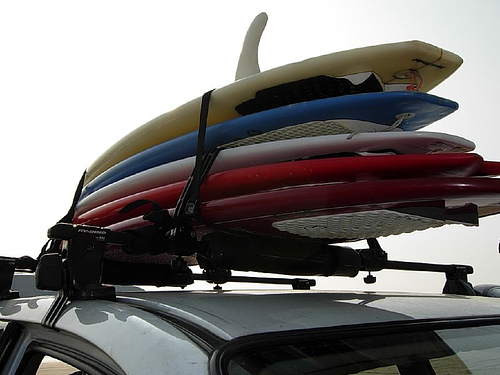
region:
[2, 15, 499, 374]
Surfboards strapped on top of car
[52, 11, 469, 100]
Yellow surfboard on top of car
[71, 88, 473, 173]
Blue surfboard on top of car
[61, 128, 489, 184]
White surfboard on top of car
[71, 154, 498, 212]
Red surfboard on top of car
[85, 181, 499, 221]
Wine colored surfboard on top of car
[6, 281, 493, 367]
Top of gray car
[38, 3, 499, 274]
White and blue sky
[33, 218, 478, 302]
Black cartop rack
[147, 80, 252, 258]
Black strap holding surfboards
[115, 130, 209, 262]
surf boards are stacked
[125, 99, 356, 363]
surf boards are stacked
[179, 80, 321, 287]
surf boards are stacked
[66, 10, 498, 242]
five surfboards strapped on top of a car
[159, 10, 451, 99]
yellow surfboard with a fin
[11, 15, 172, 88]
white colored sky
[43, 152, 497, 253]
two red surfboards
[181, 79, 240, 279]
black strap holding surfboards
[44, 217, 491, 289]
black rack on top of car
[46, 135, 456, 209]
one white surfboard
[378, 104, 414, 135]
white string on the surfboard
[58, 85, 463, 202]
one blue surfboard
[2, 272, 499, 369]
white car hauling surfboards on top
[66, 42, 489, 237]
lauguage placed on car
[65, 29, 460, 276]
objects placed on top of the car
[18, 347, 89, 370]
back door of the car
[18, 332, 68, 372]
back glass of the car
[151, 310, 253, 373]
a rubber tube in car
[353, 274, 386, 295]
a bolt on top of car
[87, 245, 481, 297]
a strong stand on car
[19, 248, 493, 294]
a stand to hold laguage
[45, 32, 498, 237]
beautiful view of sky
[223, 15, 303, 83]
top part of the laguage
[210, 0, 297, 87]
fin on top of yellow surfboard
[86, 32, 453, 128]
yellow surfboard mounted on top of car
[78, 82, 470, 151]
blue surfboard mounted on top of car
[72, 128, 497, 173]
white surfboard mounted on top of car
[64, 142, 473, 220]
red surfboard mounted on top of car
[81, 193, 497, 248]
burgundy surfboard mounted on top of car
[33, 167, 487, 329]
blak mounting brackets for surfboards on top of car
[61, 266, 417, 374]
top of white car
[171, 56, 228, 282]
straps holding surfboard together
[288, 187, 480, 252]
white no skid surface on surf board